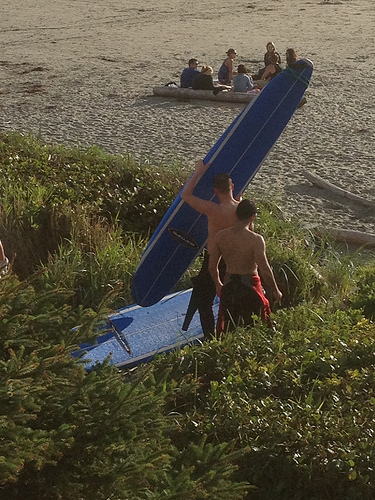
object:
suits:
[180, 251, 218, 335]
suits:
[215, 272, 271, 342]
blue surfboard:
[131, 56, 315, 309]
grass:
[0, 128, 375, 500]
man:
[208, 197, 284, 338]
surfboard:
[130, 57, 317, 310]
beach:
[0, 0, 375, 246]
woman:
[191, 62, 216, 91]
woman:
[216, 45, 237, 87]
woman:
[251, 39, 280, 79]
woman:
[282, 46, 300, 64]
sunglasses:
[229, 48, 239, 55]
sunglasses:
[193, 61, 200, 67]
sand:
[0, 0, 375, 259]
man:
[180, 157, 256, 341]